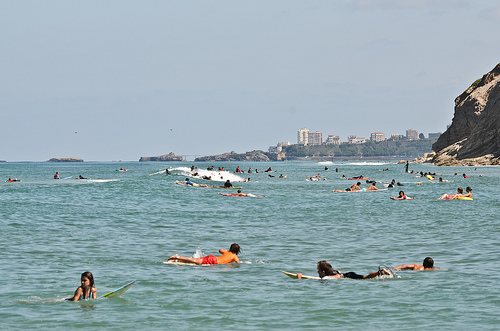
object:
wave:
[315, 159, 335, 166]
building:
[296, 126, 311, 145]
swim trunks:
[197, 255, 220, 265]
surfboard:
[96, 279, 139, 303]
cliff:
[397, 62, 500, 167]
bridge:
[177, 152, 205, 163]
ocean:
[0, 159, 500, 330]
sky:
[0, 1, 500, 162]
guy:
[296, 258, 403, 282]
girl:
[65, 270, 99, 301]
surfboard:
[279, 269, 323, 280]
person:
[403, 160, 411, 174]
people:
[164, 163, 287, 198]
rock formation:
[44, 155, 86, 164]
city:
[267, 128, 452, 150]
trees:
[282, 139, 433, 159]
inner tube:
[455, 195, 476, 200]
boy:
[166, 242, 243, 266]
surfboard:
[161, 259, 254, 267]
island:
[138, 149, 187, 162]